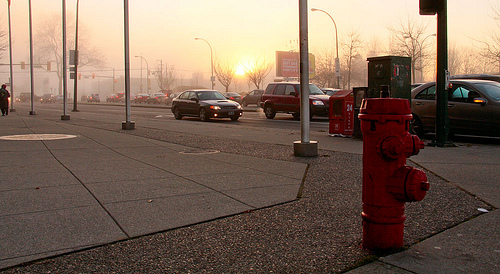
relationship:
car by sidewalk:
[418, 69, 498, 133] [95, 111, 498, 272]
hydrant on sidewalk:
[332, 80, 456, 253] [3, 108, 498, 272]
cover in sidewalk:
[179, 149, 221, 155] [3, 108, 498, 272]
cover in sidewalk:
[181, 148, 221, 155] [3, 108, 498, 272]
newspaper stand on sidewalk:
[329, 90, 354, 138] [212, 132, 361, 154]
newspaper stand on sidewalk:
[329, 90, 354, 138] [3, 108, 498, 272]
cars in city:
[178, 19, 480, 181] [7, 5, 498, 269]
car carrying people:
[411, 79, 500, 133] [166, 75, 498, 153]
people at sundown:
[196, 90, 222, 101] [200, 56, 285, 88]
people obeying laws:
[199, 92, 218, 100] [64, 44, 85, 94]